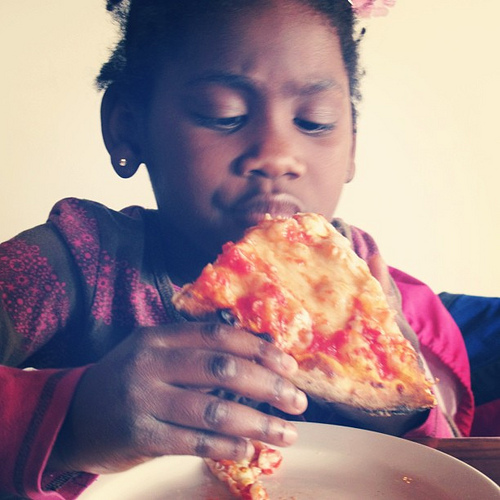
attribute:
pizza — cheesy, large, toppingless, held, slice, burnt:
[172, 210, 443, 420]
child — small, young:
[0, 3, 481, 489]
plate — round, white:
[47, 413, 498, 499]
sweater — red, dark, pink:
[3, 199, 475, 500]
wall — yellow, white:
[0, 0, 499, 313]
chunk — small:
[203, 435, 285, 500]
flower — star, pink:
[1, 239, 42, 275]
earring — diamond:
[101, 146, 146, 179]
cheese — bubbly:
[224, 238, 372, 314]